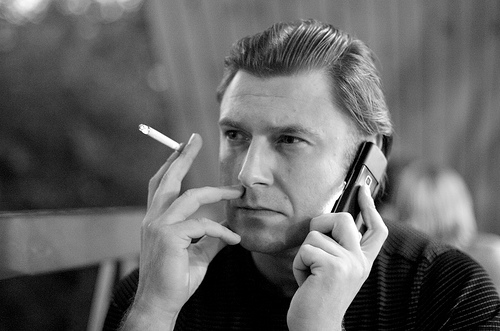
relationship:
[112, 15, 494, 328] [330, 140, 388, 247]
man with phone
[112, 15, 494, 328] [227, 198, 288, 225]
man has mouth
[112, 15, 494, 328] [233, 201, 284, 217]
man has lip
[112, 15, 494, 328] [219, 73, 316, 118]
man has fore head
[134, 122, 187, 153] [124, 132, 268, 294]
cigarrate in hand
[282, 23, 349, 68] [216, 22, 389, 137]
marks in hair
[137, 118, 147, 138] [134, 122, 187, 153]
ash on end of cigarrate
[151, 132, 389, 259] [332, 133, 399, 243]
finger on back of phone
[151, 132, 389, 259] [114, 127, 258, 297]
finger on hand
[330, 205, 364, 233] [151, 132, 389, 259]
knuckle of finger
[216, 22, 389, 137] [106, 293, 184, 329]
hair on wrist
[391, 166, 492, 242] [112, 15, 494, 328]
woman behind man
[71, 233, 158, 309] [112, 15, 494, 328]
chair behind man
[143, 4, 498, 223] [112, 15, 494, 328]
curtain behind man